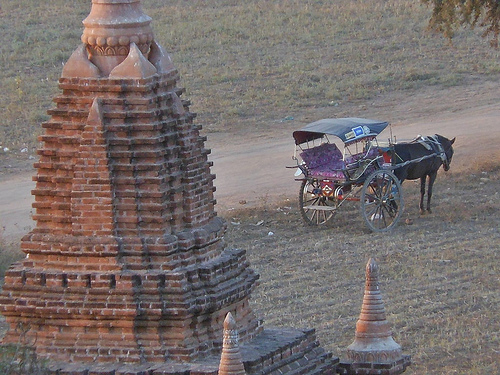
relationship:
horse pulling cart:
[380, 126, 453, 216] [290, 117, 404, 229]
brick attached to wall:
[84, 118, 106, 142] [47, 70, 174, 236]